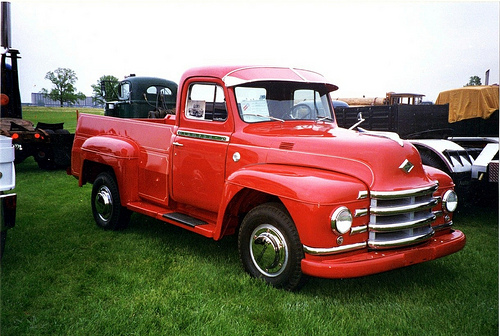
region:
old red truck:
[64, 64, 467, 278]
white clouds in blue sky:
[44, 3, 104, 33]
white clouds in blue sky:
[387, 19, 419, 61]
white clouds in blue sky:
[430, 28, 494, 69]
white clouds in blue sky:
[351, 37, 415, 81]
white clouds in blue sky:
[141, 9, 199, 64]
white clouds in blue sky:
[119, 17, 165, 42]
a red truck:
[66, 59, 470, 293]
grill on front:
[305, 177, 456, 255]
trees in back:
[42, 65, 123, 110]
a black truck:
[99, 73, 244, 118]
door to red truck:
[166, 72, 237, 224]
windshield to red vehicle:
[229, 80, 336, 125]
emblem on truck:
[398, 156, 414, 177]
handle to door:
[171, 138, 183, 150]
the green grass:
[3, 107, 499, 334]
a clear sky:
[1, 1, 498, 103]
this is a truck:
[40, 28, 496, 332]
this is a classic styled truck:
[33, 28, 494, 333]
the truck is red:
[45, 35, 462, 323]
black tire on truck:
[219, 193, 342, 312]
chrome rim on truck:
[235, 219, 307, 289]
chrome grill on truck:
[320, 148, 451, 273]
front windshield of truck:
[226, 81, 336, 128]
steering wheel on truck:
[279, 93, 320, 130]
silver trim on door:
[165, 121, 250, 156]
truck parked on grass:
[58, 54, 471, 330]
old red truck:
[52, 56, 459, 284]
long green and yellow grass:
[29, 248, 56, 267]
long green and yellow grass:
[74, 239, 112, 277]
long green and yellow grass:
[378, 281, 433, 332]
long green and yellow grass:
[213, 293, 248, 330]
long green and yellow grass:
[285, 301, 309, 325]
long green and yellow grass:
[48, 265, 94, 306]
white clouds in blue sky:
[116, 13, 152, 59]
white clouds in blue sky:
[367, 24, 426, 77]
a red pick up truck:
[68, 62, 467, 285]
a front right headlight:
[334, 207, 351, 234]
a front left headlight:
[445, 190, 457, 209]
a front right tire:
[236, 206, 304, 291]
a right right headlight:
[89, 173, 127, 228]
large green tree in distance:
[44, 65, 78, 105]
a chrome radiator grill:
[369, 180, 436, 248]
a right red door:
[171, 74, 234, 211]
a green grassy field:
[0, 106, 498, 333]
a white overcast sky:
[1, 0, 498, 101]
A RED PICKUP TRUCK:
[65, 63, 470, 295]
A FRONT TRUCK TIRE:
[234, 197, 305, 294]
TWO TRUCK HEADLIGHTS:
[326, 187, 462, 239]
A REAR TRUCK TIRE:
[88, 170, 126, 233]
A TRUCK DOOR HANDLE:
[170, 138, 184, 148]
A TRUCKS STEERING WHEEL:
[278, 100, 318, 122]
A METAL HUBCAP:
[246, 220, 291, 280]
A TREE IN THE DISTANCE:
[40, 65, 77, 110]